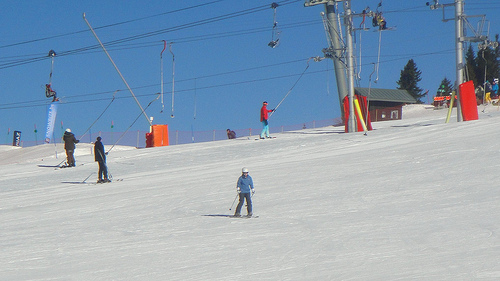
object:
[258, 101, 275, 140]
he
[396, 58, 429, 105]
tree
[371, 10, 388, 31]
skier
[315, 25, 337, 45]
lift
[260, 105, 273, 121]
coat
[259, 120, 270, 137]
pant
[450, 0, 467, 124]
pole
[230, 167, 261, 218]
person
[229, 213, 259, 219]
ski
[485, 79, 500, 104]
sign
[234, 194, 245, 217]
leg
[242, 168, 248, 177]
head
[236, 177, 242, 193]
arm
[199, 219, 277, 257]
snow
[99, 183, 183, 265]
plain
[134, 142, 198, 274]
slope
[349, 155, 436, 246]
mountain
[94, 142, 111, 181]
clothe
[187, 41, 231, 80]
cloud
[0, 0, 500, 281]
photo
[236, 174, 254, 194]
jacket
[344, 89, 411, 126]
house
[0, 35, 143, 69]
cable